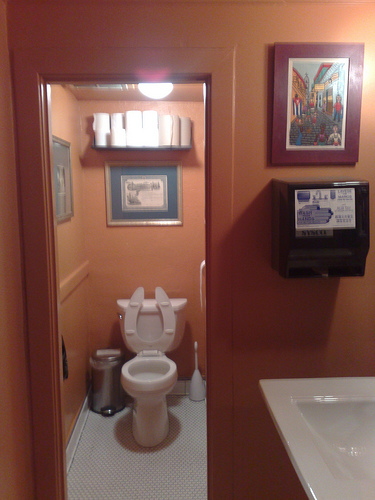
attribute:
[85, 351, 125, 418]
can — silver, steel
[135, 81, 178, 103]
light — on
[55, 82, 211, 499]
bathroom — clean, well-lit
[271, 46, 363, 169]
picture — framed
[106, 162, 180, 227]
picture — framed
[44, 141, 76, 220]
picture — framed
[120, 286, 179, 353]
seat — open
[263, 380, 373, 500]
sink — white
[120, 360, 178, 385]
bowl — clean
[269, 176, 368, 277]
towel holder — black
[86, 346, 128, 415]
basket — metal, waste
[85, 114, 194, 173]
brush — white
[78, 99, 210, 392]
wall — orange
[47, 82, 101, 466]
wall — orange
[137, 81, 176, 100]
light — hanging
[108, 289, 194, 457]
toilet bowl — white, porcelain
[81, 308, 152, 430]
trash can — stainless steel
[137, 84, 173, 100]
light — turned on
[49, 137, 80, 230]
picture — hanging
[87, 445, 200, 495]
floor — grey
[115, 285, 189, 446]
toilet — white, up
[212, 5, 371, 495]
wall — orange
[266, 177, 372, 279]
dispenser — black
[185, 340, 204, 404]
toilet scrubber — white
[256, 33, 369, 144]
art — framed